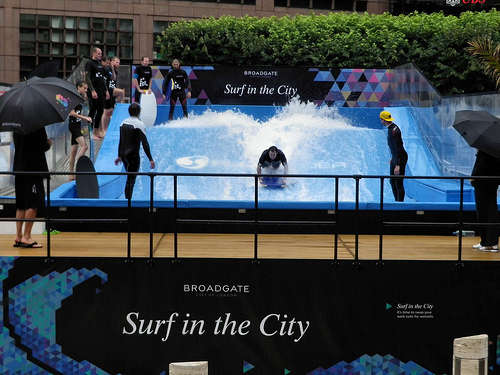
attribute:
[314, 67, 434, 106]
decoration — colorful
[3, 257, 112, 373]
decoration — colorful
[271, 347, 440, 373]
decoration — colorful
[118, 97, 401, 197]
water — running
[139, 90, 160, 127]
surf board — white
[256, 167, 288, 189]
surf board — black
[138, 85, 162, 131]
surfboard — white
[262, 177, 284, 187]
surfboard — blue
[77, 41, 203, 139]
people — waiting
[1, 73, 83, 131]
umbrella — black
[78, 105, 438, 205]
pool — public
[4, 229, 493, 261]
flooring — wooden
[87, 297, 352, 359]
writing — white